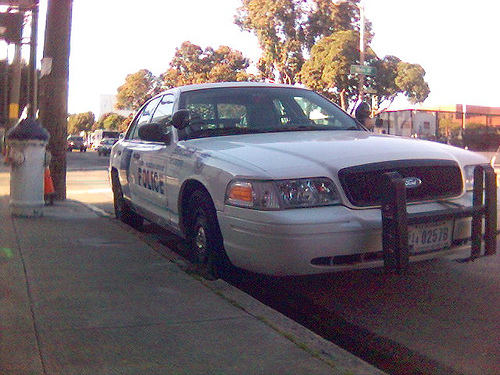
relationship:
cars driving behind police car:
[68, 126, 121, 153] [106, 81, 497, 288]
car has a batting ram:
[109, 81, 492, 279] [384, 180, 483, 250]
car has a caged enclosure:
[109, 81, 492, 279] [198, 106, 214, 123]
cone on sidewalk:
[42, 161, 56, 201] [31, 222, 155, 355]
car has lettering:
[109, 81, 492, 279] [134, 164, 168, 194]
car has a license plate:
[109, 81, 492, 279] [412, 224, 463, 248]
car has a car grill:
[109, 81, 492, 279] [342, 164, 461, 207]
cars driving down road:
[67, 135, 89, 152] [75, 153, 105, 193]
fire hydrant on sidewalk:
[6, 109, 48, 213] [19, 220, 159, 365]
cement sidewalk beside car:
[0, 201, 350, 365] [109, 81, 492, 279]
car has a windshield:
[109, 81, 492, 279] [184, 89, 349, 133]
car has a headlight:
[109, 81, 492, 279] [249, 174, 336, 209]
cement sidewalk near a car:
[0, 201, 350, 365] [109, 81, 492, 279]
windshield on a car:
[183, 87, 350, 129] [104, 89, 482, 278]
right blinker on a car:
[225, 182, 262, 205] [109, 81, 492, 279]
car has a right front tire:
[109, 81, 492, 279] [181, 188, 223, 280]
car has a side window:
[109, 81, 492, 279] [148, 100, 172, 121]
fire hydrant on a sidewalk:
[6, 117, 53, 218] [34, 231, 158, 332]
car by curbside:
[109, 81, 492, 279] [113, 217, 171, 263]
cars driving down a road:
[73, 135, 108, 155] [75, 153, 105, 193]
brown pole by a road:
[40, 2, 71, 201] [75, 153, 105, 193]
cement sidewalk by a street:
[0, 201, 350, 365] [345, 283, 451, 348]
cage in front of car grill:
[373, 171, 483, 268] [353, 178, 377, 199]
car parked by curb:
[104, 89, 482, 278] [224, 290, 306, 357]